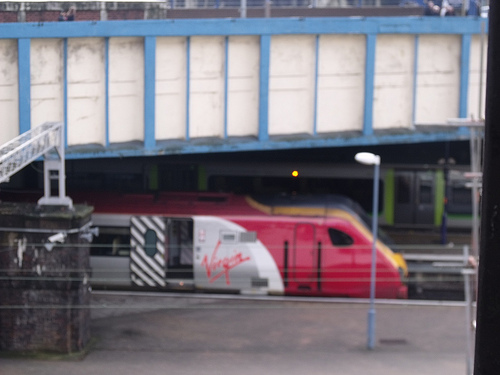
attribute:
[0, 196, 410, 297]
train — white, tan, red, yellow, orange, blue, grey, gray, moving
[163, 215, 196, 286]
door — open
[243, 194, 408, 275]
stripe — yellow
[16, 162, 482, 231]
train — green, grey, moving, silver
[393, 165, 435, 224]
doors — closed, gray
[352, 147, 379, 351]
street light — white, gray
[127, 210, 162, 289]
door — black, white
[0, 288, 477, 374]
sidewalk — gray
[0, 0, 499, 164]
bridge — blue, white, metal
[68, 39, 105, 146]
panel — white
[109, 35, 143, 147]
panel — white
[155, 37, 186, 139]
panel — white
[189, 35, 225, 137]
panel — white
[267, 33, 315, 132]
panel — white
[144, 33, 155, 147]
support — blue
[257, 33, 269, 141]
support — blue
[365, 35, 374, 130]
support — blue